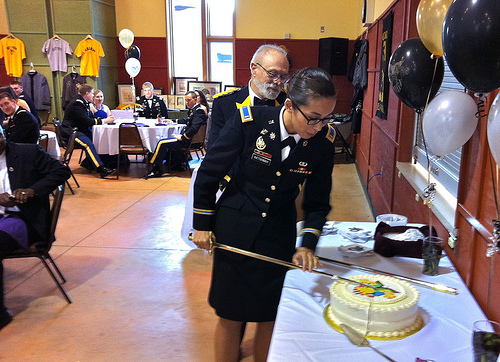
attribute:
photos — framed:
[112, 63, 245, 113]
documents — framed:
[103, 66, 259, 119]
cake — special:
[326, 267, 427, 343]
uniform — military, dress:
[55, 92, 105, 174]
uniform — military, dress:
[13, 92, 45, 133]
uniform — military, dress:
[0, 102, 43, 146]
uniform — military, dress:
[0, 139, 72, 311]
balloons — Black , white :
[380, 17, 498, 176]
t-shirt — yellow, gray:
[41, 35, 76, 77]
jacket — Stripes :
[186, 104, 347, 269]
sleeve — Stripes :
[193, 100, 243, 242]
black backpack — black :
[352, 40, 367, 90]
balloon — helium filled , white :
[384, 83, 499, 159]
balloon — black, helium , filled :
[388, 37, 445, 114]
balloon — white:
[422, 88, 477, 155]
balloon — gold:
[416, 0, 453, 57]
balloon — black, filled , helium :
[441, 0, 498, 97]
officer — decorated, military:
[190, 65, 341, 360]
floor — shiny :
[11, 138, 453, 358]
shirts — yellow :
[8, 34, 108, 82]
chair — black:
[117, 123, 150, 175]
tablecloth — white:
[93, 122, 182, 153]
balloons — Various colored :
[382, 0, 496, 259]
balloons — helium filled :
[385, 9, 498, 227]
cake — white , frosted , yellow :
[321, 268, 430, 341]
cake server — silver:
[337, 320, 397, 360]